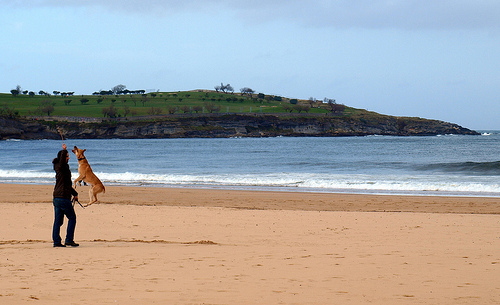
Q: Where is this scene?
A: On the beach.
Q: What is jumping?
A: A dog.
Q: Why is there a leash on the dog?
A: To keep it from running off.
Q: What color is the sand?
A: Brown.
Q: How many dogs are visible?
A: One.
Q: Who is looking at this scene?
A: The photographer.